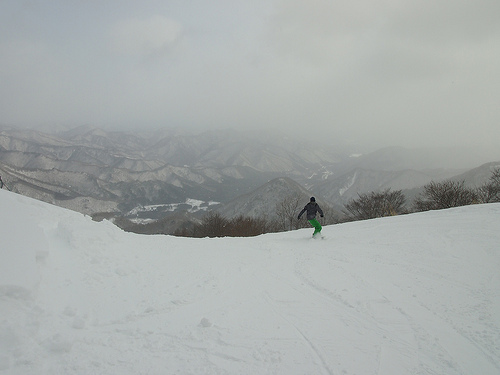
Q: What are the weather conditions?
A: It is cloudy.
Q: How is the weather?
A: It is cloudy.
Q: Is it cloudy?
A: Yes, it is cloudy.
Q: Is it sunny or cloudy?
A: It is cloudy.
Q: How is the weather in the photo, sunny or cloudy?
A: It is cloudy.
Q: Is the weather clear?
A: No, it is cloudy.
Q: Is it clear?
A: No, it is cloudy.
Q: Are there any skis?
A: No, there are no skis.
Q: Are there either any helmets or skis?
A: No, there are no skis or helmets.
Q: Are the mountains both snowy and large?
A: Yes, the mountains are snowy and large.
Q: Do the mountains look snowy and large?
A: Yes, the mountains are snowy and large.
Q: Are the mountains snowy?
A: Yes, the mountains are snowy.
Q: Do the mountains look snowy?
A: Yes, the mountains are snowy.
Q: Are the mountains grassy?
A: No, the mountains are snowy.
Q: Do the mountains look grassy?
A: No, the mountains are snowy.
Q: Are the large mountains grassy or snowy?
A: The mountains are snowy.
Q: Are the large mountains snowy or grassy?
A: The mountains are snowy.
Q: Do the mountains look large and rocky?
A: No, the mountains are large but snowy.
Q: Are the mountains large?
A: Yes, the mountains are large.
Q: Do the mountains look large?
A: Yes, the mountains are large.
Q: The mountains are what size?
A: The mountains are large.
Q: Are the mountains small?
A: No, the mountains are large.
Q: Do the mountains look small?
A: No, the mountains are large.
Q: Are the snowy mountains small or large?
A: The mountains are large.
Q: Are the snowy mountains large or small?
A: The mountains are large.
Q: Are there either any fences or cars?
A: No, there are no cars or fences.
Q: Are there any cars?
A: No, there are no cars.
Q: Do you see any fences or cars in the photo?
A: No, there are no cars or fences.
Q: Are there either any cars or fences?
A: No, there are no cars or fences.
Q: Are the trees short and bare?
A: Yes, the trees are short and bare.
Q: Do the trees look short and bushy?
A: No, the trees are short but bare.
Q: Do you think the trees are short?
A: Yes, the trees are short.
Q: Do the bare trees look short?
A: Yes, the trees are short.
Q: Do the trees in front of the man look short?
A: Yes, the trees are short.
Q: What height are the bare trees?
A: The trees are short.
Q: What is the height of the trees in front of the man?
A: The trees are short.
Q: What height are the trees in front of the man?
A: The trees are short.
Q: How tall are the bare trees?
A: The trees are short.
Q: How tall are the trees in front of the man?
A: The trees are short.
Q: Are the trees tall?
A: No, the trees are short.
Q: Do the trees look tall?
A: No, the trees are short.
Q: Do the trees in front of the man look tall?
A: No, the trees are short.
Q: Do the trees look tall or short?
A: The trees are short.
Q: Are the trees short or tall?
A: The trees are short.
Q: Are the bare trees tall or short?
A: The trees are short.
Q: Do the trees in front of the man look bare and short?
A: Yes, the trees are bare and short.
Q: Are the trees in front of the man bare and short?
A: Yes, the trees are bare and short.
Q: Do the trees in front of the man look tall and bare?
A: No, the trees are bare but short.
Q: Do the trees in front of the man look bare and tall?
A: No, the trees are bare but short.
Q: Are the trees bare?
A: Yes, the trees are bare.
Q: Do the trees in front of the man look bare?
A: Yes, the trees are bare.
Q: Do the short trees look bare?
A: Yes, the trees are bare.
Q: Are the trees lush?
A: No, the trees are bare.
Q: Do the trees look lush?
A: No, the trees are bare.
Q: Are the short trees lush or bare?
A: The trees are bare.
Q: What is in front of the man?
A: The trees are in front of the man.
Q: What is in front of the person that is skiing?
A: The trees are in front of the man.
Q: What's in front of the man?
A: The trees are in front of the man.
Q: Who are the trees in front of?
A: The trees are in front of the man.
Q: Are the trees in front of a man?
A: Yes, the trees are in front of a man.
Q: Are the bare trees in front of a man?
A: Yes, the trees are in front of a man.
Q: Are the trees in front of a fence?
A: No, the trees are in front of a man.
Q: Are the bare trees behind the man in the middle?
A: No, the trees are in front of the man.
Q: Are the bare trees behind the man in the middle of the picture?
A: No, the trees are in front of the man.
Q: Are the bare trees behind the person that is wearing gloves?
A: No, the trees are in front of the man.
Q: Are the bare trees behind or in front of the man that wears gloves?
A: The trees are in front of the man.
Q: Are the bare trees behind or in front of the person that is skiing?
A: The trees are in front of the man.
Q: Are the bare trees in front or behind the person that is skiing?
A: The trees are in front of the man.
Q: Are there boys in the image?
A: No, there are no boys.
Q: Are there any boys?
A: No, there are no boys.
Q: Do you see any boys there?
A: No, there are no boys.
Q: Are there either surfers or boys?
A: No, there are no boys or surfers.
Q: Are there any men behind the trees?
A: Yes, there is a man behind the trees.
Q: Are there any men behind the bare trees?
A: Yes, there is a man behind the trees.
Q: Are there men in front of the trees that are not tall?
A: No, the man is behind the trees.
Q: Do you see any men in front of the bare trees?
A: No, the man is behind the trees.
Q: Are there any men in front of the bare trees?
A: No, the man is behind the trees.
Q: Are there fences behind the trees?
A: No, there is a man behind the trees.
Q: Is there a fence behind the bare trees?
A: No, there is a man behind the trees.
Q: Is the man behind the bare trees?
A: Yes, the man is behind the trees.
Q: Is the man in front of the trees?
A: No, the man is behind the trees.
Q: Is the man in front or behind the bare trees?
A: The man is behind the trees.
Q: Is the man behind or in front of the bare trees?
A: The man is behind the trees.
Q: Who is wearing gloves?
A: The man is wearing gloves.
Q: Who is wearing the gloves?
A: The man is wearing gloves.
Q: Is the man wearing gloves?
A: Yes, the man is wearing gloves.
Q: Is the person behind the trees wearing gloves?
A: Yes, the man is wearing gloves.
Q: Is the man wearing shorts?
A: No, the man is wearing gloves.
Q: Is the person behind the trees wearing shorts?
A: No, the man is wearing gloves.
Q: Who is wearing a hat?
A: The man is wearing a hat.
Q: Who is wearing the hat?
A: The man is wearing a hat.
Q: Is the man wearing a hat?
A: Yes, the man is wearing a hat.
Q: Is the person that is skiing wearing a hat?
A: Yes, the man is wearing a hat.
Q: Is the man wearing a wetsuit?
A: No, the man is wearing a hat.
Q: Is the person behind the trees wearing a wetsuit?
A: No, the man is wearing a hat.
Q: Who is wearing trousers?
A: The man is wearing trousers.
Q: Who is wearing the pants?
A: The man is wearing trousers.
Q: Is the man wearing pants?
A: Yes, the man is wearing pants.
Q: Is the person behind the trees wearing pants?
A: Yes, the man is wearing pants.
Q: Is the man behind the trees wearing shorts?
A: No, the man is wearing pants.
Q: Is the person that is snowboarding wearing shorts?
A: No, the man is wearing pants.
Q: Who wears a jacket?
A: The man wears a jacket.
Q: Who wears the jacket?
A: The man wears a jacket.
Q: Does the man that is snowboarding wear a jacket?
A: Yes, the man wears a jacket.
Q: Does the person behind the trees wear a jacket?
A: Yes, the man wears a jacket.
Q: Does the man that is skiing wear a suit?
A: No, the man wears a jacket.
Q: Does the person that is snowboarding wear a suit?
A: No, the man wears a jacket.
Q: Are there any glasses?
A: No, there are no glasses.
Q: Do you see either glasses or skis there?
A: No, there are no glasses or skis.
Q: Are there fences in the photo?
A: No, there are no fences.